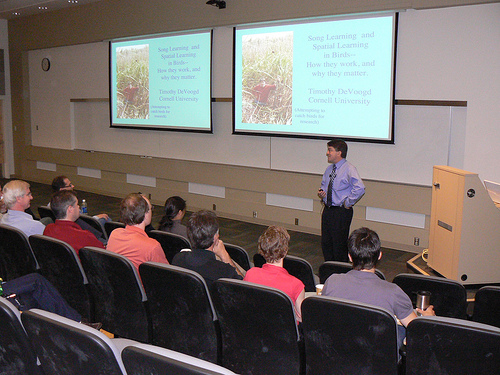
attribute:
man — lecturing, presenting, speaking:
[317, 139, 366, 263]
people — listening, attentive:
[0, 176, 438, 359]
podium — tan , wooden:
[425, 164, 499, 285]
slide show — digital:
[108, 11, 399, 145]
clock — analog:
[41, 56, 50, 73]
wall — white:
[0, 0, 499, 260]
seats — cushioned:
[0, 204, 500, 374]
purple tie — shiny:
[327, 164, 337, 208]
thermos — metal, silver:
[414, 291, 432, 315]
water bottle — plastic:
[81, 197, 89, 213]